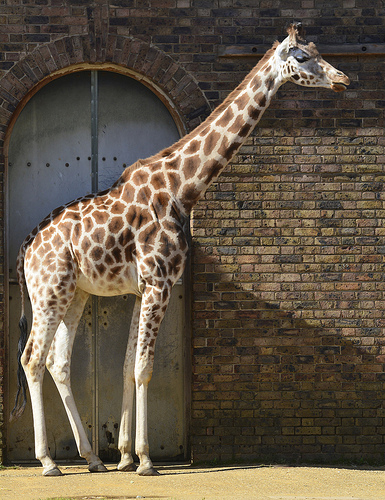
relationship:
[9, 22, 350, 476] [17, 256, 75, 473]
giraffe has leg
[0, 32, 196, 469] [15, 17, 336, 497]
archway behind giraffe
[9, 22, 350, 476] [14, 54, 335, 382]
giraffe has spots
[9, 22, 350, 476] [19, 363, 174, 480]
giraffe has legs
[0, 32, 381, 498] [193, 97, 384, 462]
sunshine on brick wall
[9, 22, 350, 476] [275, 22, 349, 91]
giraffe on giraffe head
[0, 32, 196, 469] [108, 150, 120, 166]
archway has rivet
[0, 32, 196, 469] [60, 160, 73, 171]
archway has rivet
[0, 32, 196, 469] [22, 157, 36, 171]
archway has rivet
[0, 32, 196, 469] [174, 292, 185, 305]
archway has rivet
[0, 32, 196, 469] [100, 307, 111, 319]
archway has rivet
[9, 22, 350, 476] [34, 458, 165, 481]
giraffe has hoofs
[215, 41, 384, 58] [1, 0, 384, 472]
wood against brick wall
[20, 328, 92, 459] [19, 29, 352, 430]
legs of giraffe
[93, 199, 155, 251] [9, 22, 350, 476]
skin of giraffe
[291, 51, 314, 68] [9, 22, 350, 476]
eye of giraffe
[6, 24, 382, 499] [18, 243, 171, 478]
sunshine falling on legs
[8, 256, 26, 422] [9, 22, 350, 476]
tail of giraffe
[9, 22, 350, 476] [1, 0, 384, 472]
giraffe standing in front of brick wall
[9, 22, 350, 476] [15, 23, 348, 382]
giraffe with spots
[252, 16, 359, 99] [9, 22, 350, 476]
spotted head of giraffe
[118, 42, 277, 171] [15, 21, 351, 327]
giraffe mane on back of giraffes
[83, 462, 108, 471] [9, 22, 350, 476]
hoof on giraffe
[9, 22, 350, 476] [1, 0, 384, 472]
giraffe standing by brick wall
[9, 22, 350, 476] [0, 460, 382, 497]
giraffe standing on ground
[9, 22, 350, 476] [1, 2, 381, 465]
giraffe standing next to building